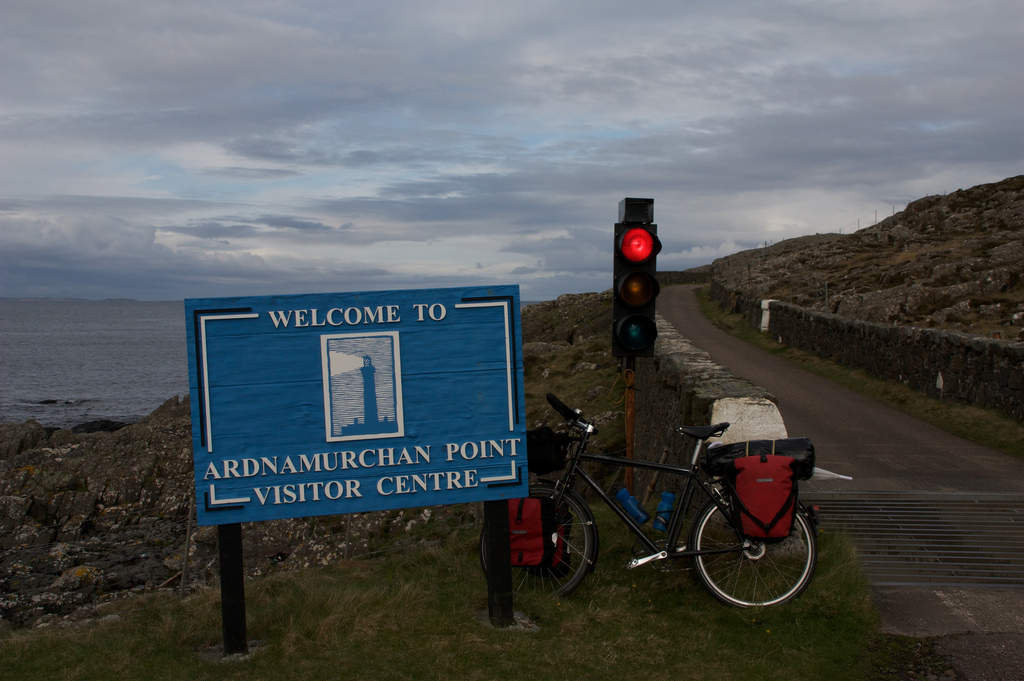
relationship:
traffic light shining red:
[608, 196, 658, 354] [623, 228, 652, 261]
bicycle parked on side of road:
[481, 393, 815, 609] [670, 284, 993, 667]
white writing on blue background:
[266, 298, 455, 329] [186, 285, 530, 519]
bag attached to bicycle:
[717, 448, 806, 537] [543, 400, 799, 604]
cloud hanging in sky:
[158, 139, 288, 170] [4, 3, 992, 302]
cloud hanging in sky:
[264, 154, 515, 217] [4, 3, 992, 302]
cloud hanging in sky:
[505, 18, 832, 131] [4, 3, 992, 302]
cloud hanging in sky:
[646, 175, 910, 240] [4, 3, 992, 302]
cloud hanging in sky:
[4, 147, 179, 200] [4, 3, 992, 302]